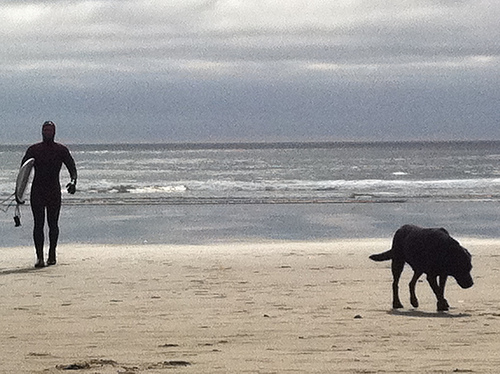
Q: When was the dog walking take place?
A: Daytime.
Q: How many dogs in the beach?
A: One.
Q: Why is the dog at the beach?
A: To walk.